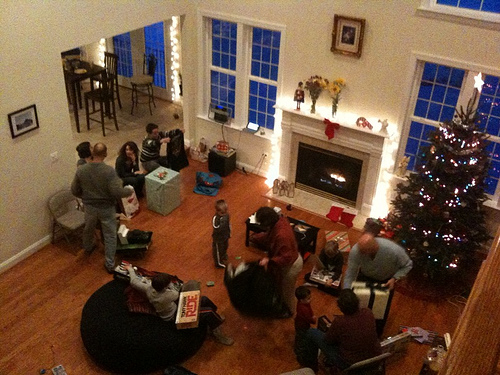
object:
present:
[403, 117, 488, 274]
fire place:
[262, 104, 390, 234]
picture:
[329, 12, 367, 59]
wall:
[187, 0, 500, 240]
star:
[472, 71, 485, 93]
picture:
[7, 102, 41, 140]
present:
[348, 281, 392, 321]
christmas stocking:
[338, 205, 359, 228]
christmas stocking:
[324, 201, 345, 222]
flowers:
[327, 84, 340, 96]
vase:
[310, 99, 316, 114]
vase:
[332, 105, 339, 118]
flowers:
[312, 79, 321, 88]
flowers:
[338, 78, 344, 84]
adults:
[70, 140, 136, 274]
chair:
[130, 73, 157, 117]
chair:
[83, 74, 121, 138]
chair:
[335, 350, 394, 374]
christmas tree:
[384, 72, 500, 289]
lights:
[452, 186, 460, 195]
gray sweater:
[342, 236, 413, 292]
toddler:
[210, 196, 234, 269]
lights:
[444, 134, 449, 141]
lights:
[424, 170, 430, 176]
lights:
[426, 229, 433, 234]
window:
[195, 9, 286, 142]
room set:
[129, 52, 157, 117]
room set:
[62, 58, 110, 134]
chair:
[46, 188, 105, 257]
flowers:
[323, 79, 330, 85]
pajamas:
[210, 213, 232, 267]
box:
[143, 165, 182, 217]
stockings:
[339, 204, 360, 227]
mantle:
[279, 99, 399, 139]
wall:
[0, 0, 188, 273]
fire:
[330, 173, 347, 183]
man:
[340, 233, 414, 339]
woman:
[246, 205, 304, 315]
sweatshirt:
[211, 211, 231, 244]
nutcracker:
[355, 116, 374, 130]